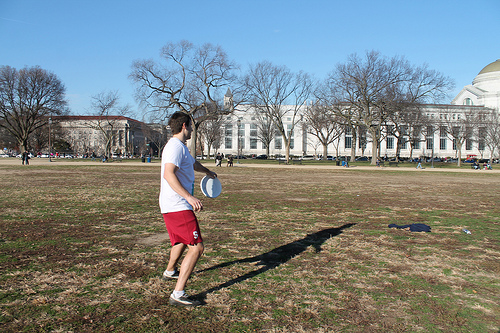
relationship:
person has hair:
[150, 108, 209, 308] [162, 106, 201, 144]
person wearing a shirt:
[150, 108, 209, 308] [157, 133, 204, 214]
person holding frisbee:
[150, 108, 209, 308] [193, 172, 229, 200]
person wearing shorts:
[150, 108, 209, 308] [163, 208, 210, 247]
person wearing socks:
[150, 108, 209, 308] [160, 264, 188, 296]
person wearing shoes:
[150, 108, 209, 308] [163, 261, 197, 311]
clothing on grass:
[384, 220, 437, 240] [355, 240, 484, 309]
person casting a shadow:
[150, 108, 209, 308] [185, 215, 366, 305]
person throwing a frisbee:
[150, 108, 209, 308] [193, 172, 229, 200]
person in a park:
[150, 108, 209, 308] [1, 0, 500, 333]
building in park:
[184, 57, 499, 158] [1, 0, 500, 333]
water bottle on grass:
[453, 223, 481, 242] [355, 240, 484, 309]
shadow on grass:
[185, 215, 366, 305] [355, 240, 484, 309]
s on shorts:
[187, 228, 209, 248] [163, 208, 210, 247]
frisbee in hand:
[193, 172, 229, 200] [201, 168, 228, 180]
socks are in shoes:
[160, 264, 188, 296] [163, 261, 197, 311]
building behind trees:
[184, 57, 499, 158] [1, 41, 497, 173]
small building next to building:
[9, 108, 157, 161] [184, 57, 499, 158]